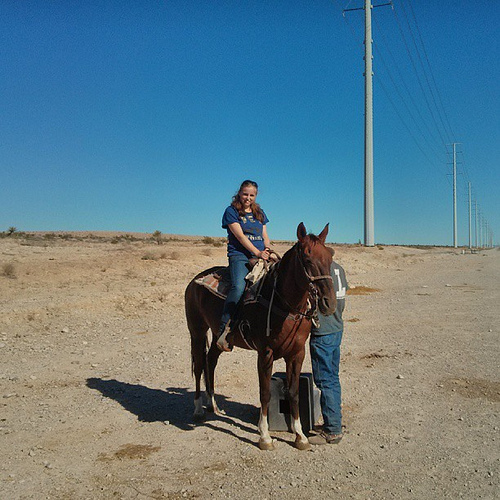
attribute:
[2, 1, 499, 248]
sky — bright, blue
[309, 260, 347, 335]
t-shirt — army green, grey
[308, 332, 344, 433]
jeans — blue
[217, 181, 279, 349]
woman — the rider, holding the reins, not experienced ride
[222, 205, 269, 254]
shirt — blue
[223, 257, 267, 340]
jeans — blue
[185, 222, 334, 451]
horse — brown, chestnut, a bay quarter, in the picture, present, pictured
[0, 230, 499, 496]
ground — dry, stoney, very barren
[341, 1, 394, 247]
post — big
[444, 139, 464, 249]
post — big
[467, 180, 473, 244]
post — big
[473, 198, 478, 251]
post — big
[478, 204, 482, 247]
post — big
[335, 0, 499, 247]
power lines — in the background, utility lines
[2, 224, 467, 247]
vegetation — sparse, along the horizon